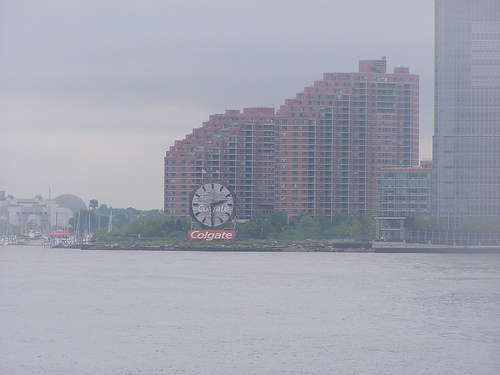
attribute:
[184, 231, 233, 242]
sign — red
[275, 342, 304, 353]
ripples — small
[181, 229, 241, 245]
sign — red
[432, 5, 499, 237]
skyscraper — tall, grey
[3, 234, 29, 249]
boat — floating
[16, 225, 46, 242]
boat — floating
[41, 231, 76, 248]
boat — floating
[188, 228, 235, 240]
sign — red, white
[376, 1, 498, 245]
building — tall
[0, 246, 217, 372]
ripples — small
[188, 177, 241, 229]
clock — large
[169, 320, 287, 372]
ripples — small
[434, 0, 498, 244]
building — tall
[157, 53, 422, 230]
building — red, tall, brick, large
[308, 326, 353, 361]
ripples — small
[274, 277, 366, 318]
ripples — small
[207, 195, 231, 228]
hands — black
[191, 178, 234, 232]
face — clear, round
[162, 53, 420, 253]
building — brick